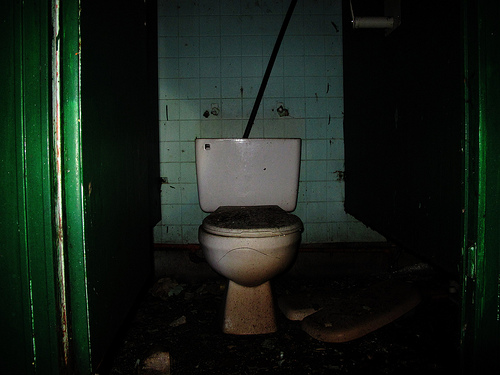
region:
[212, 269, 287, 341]
white toilet stand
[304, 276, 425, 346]
white toilet tank lid on the dirty floor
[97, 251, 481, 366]
trash and dirt on the floor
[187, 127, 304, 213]
white toilet tank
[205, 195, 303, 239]
white toilet lid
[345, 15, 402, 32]
toilet paper roll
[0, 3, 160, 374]
green stall door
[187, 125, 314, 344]
white toilet in a dirty bathroom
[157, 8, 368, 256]
dirty white tile behind the toilet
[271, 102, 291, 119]
missing tile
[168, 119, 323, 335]
The toilet is white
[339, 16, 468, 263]
The stall door is green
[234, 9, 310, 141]
the pole is black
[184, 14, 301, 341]
The pole is behind the toilet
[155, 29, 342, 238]
The tile has grime and dirt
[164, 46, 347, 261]
The tile is square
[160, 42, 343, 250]
The tile is green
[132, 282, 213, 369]
Trash on the ground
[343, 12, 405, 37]
The metal is grey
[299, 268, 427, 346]
Brown lid on the floor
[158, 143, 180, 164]
This is a tile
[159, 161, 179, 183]
This is a tile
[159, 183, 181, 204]
This is a tile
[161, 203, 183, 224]
This is a tile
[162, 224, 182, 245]
This is a tile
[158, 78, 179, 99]
This is a tile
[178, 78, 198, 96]
This is a tile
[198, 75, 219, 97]
This is a tile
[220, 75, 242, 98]
This is a tile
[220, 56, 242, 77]
This is a tile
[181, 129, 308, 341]
a white toilet in a dirty bathroom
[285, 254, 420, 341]
lid to the toilet tank on the floor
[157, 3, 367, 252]
white tile wall behind the toilet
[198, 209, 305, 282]
white toilet bowl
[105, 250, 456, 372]
dirt and garbage covered floor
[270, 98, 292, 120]
chip in the tile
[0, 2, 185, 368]
green stall door of the bathroom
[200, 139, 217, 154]
hole where the handle used to be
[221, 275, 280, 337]
base of the toilet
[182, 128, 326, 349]
white porcelain toilet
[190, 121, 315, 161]
no lid on the top of the toilet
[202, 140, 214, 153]
small blach hole where the handle used to be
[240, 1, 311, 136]
thin black pole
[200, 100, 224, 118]
dark marks on the wall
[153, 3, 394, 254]
wall behind the toilet is tiled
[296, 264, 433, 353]
something laying on the ground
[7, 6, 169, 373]
emerald green structure of the stall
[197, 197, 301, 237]
something is on the toilet seat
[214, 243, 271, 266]
black line on the toilet